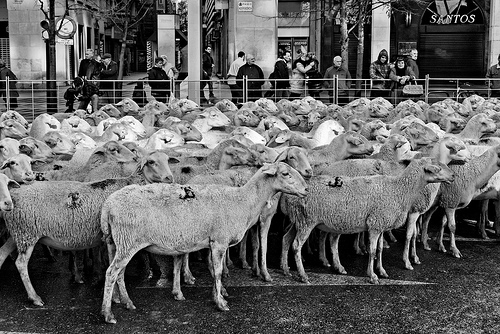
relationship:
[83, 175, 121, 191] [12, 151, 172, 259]
black spot on goat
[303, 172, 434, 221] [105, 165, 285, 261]
sheep standing sheep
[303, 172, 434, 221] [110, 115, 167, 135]
sheep standing sheep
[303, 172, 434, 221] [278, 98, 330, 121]
sheep standing sheep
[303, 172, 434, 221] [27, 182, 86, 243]
sheep standing sheep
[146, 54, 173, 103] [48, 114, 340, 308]
person standing behind sheep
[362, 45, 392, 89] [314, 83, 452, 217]
person standing behind sheep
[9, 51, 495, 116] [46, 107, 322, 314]
fene between people and sheep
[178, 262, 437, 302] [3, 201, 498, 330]
white arrow painted on floor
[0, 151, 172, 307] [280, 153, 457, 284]
goat looking towards sheep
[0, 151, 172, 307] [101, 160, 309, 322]
goat looking towards sheep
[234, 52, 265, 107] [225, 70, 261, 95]
man wearing jacket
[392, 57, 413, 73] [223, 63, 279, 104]
person wearing jacket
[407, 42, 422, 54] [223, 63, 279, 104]
person wearing jacket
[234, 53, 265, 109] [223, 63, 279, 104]
man wearing jacket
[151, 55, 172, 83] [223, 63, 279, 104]
person wearing jacket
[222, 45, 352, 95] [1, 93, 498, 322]
people looking at sheep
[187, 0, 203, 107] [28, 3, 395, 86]
pillar of a building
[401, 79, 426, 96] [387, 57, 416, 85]
purse of a person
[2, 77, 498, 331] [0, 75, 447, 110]
goats behind fence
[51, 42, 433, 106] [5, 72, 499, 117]
people on other side of fence